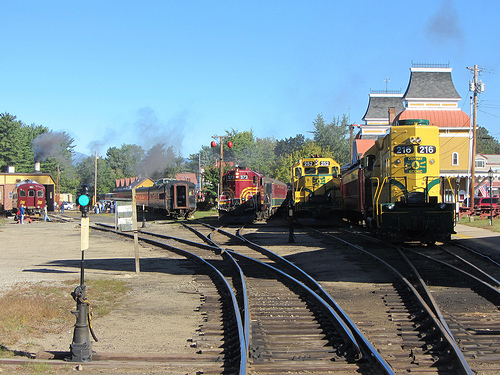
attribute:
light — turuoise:
[219, 135, 226, 207]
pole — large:
[209, 140, 233, 148]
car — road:
[216, 163, 289, 224]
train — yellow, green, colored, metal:
[288, 153, 348, 225]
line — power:
[467, 62, 499, 121]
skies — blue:
[2, 0, 500, 165]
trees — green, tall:
[1, 112, 350, 206]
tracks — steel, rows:
[34, 212, 499, 374]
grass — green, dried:
[0, 273, 137, 373]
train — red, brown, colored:
[217, 165, 290, 225]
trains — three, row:
[216, 121, 457, 245]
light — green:
[78, 192, 93, 206]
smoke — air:
[31, 109, 188, 183]